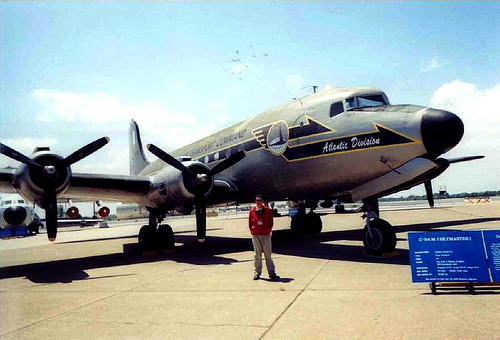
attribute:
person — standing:
[230, 195, 317, 291]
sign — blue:
[406, 226, 499, 284]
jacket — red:
[248, 207, 273, 234]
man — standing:
[249, 193, 279, 278]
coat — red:
[230, 197, 312, 264]